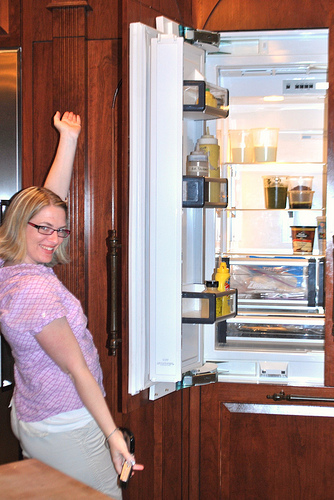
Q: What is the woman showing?
A: A refrigerator.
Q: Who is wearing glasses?
A: A woman.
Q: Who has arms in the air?
A: A woman.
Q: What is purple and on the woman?
A: A blouse.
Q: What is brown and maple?
A: A cabinet.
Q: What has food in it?
A: A refridgerator.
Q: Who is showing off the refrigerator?
A: A woman.